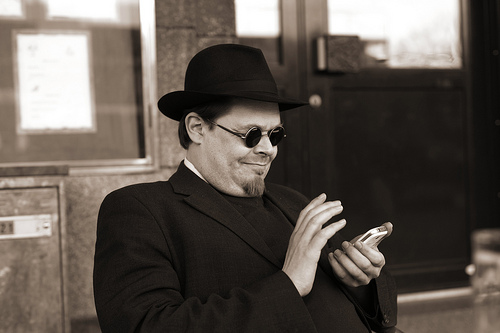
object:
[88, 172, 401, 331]
suit jacket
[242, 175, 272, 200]
beard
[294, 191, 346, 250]
fingers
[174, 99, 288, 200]
head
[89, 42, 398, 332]
man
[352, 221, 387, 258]
cell phone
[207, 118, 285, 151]
goggles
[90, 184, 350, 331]
arm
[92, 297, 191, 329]
elbow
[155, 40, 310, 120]
black hat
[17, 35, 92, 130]
sign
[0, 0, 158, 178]
window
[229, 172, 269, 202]
chin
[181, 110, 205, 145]
ear